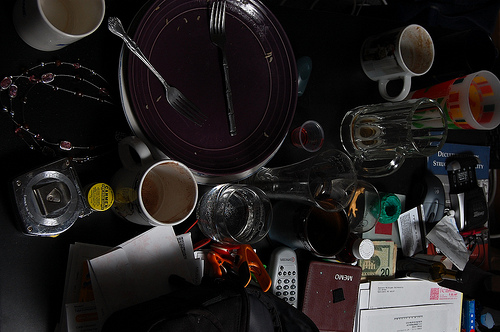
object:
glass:
[196, 182, 274, 246]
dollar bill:
[359, 240, 397, 283]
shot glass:
[291, 120, 325, 152]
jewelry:
[0, 59, 111, 150]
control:
[272, 247, 298, 308]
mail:
[353, 280, 463, 331]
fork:
[209, 1, 236, 136]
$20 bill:
[359, 241, 394, 283]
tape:
[24, 170, 78, 226]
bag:
[139, 274, 321, 331]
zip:
[238, 255, 251, 286]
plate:
[116, 0, 297, 186]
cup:
[111, 136, 199, 226]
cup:
[361, 24, 435, 102]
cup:
[19, 0, 106, 51]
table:
[0, 0, 499, 332]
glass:
[339, 97, 448, 178]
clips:
[207, 245, 272, 293]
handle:
[353, 155, 405, 177]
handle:
[379, 74, 412, 102]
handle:
[118, 136, 153, 173]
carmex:
[87, 183, 114, 212]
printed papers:
[356, 280, 463, 332]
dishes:
[340, 98, 449, 178]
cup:
[406, 70, 496, 130]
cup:
[196, 183, 273, 245]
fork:
[108, 17, 209, 127]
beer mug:
[340, 97, 449, 178]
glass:
[256, 148, 357, 212]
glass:
[330, 178, 382, 233]